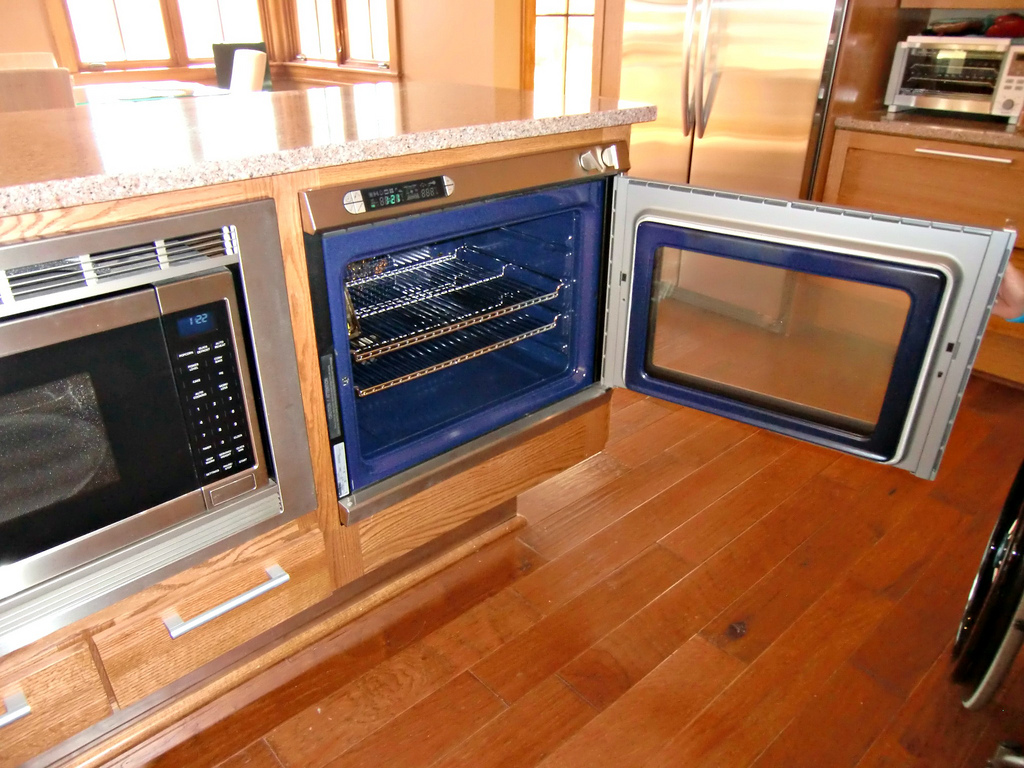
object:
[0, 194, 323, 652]
microwave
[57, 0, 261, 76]
windows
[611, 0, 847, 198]
refrigerator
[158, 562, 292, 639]
handle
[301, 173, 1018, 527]
oven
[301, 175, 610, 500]
blue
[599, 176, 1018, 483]
door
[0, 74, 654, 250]
top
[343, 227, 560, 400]
racks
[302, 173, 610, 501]
interior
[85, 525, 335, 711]
drawer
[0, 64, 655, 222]
countertop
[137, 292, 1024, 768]
flooring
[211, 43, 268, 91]
chair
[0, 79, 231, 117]
table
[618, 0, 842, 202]
doors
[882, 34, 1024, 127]
oven